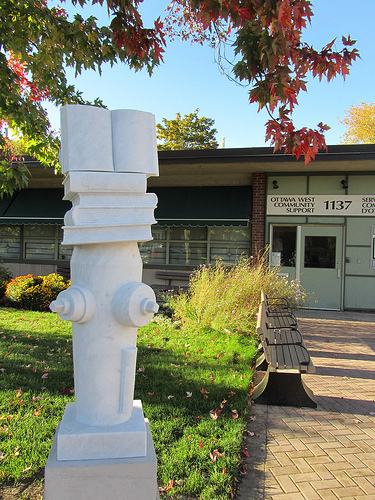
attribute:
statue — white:
[38, 101, 158, 490]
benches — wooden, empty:
[255, 295, 312, 407]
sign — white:
[268, 195, 374, 215]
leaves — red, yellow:
[266, 3, 326, 159]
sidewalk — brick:
[266, 308, 370, 498]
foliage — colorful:
[191, 6, 363, 160]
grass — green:
[8, 308, 253, 492]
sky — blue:
[74, 0, 370, 132]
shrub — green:
[12, 273, 69, 312]